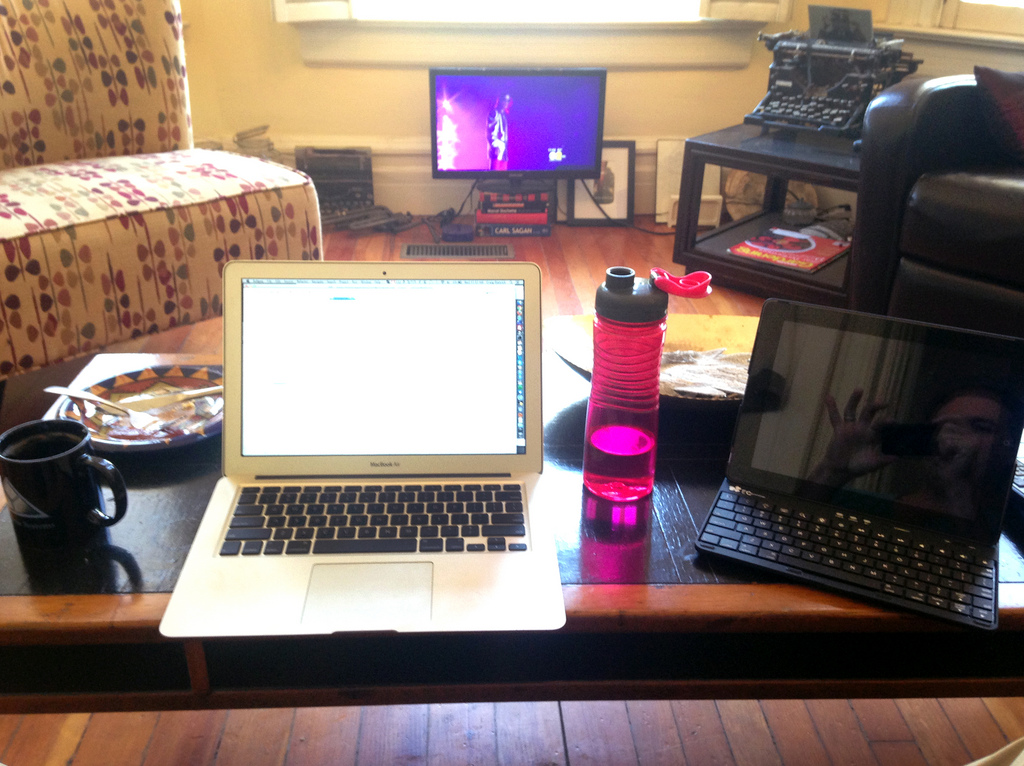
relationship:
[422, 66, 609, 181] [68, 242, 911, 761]
tv on floor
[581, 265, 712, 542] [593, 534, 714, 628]
water bottle on table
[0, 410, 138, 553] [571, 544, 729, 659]
mug on table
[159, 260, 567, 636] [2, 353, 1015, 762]
laptop on desk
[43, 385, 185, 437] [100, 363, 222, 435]
fork on plate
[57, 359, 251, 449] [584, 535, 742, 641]
plate on table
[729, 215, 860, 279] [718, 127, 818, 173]
book under table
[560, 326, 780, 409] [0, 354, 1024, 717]
bowl on desk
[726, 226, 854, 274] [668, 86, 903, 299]
book under table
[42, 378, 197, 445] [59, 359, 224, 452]
fork on plate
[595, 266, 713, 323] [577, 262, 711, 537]
top on water bottle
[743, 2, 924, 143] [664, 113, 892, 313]
typewriter on table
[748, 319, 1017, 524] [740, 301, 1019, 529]
screen in screen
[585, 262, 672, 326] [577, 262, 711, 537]
top on water bottle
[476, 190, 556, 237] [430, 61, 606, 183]
books under tv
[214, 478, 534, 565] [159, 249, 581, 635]
keys on laptop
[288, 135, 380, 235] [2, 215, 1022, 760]
radio on floor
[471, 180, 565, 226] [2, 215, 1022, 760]
books are on floor